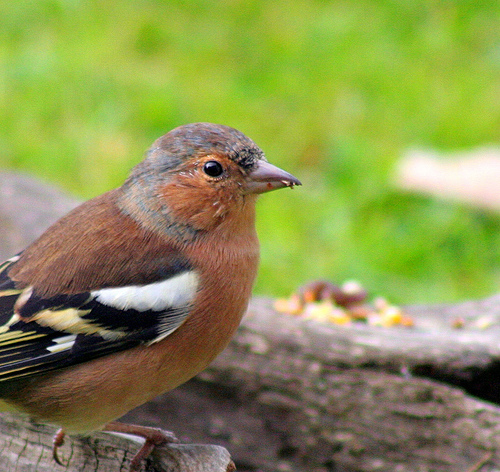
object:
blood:
[267, 183, 273, 190]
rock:
[2, 414, 233, 470]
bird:
[0, 121, 301, 469]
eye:
[203, 160, 223, 178]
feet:
[88, 423, 177, 471]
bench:
[1, 420, 237, 472]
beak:
[251, 156, 303, 195]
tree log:
[2, 167, 499, 468]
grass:
[0, 5, 497, 305]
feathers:
[0, 266, 199, 385]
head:
[140, 122, 301, 236]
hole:
[378, 353, 498, 412]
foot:
[390, 138, 499, 218]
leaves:
[227, 80, 364, 188]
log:
[2, 172, 496, 470]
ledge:
[0, 170, 496, 470]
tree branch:
[2, 170, 498, 470]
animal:
[2, 122, 303, 466]